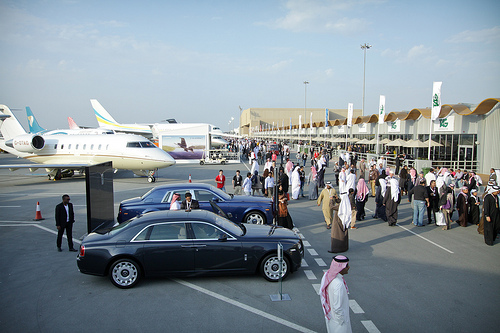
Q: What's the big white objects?
A: Airplanes.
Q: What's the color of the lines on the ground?
A: White.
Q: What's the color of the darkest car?
A: Black.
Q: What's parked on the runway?
A: Airplane.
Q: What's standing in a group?
A: The people.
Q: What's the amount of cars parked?
A: Two.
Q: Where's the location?
A: Airport.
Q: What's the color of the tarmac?
A: Gray.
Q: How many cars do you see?
A: 2.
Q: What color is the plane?
A: White.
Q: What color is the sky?
A: Blue.